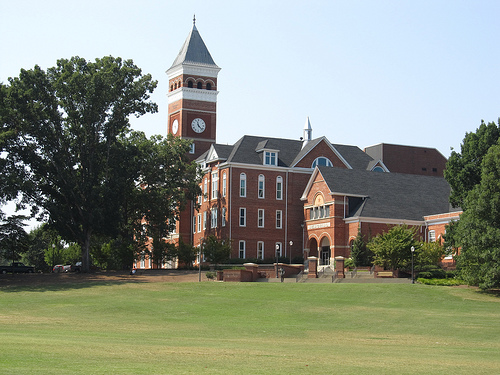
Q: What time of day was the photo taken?
A: Daytime.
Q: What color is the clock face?
A: White.